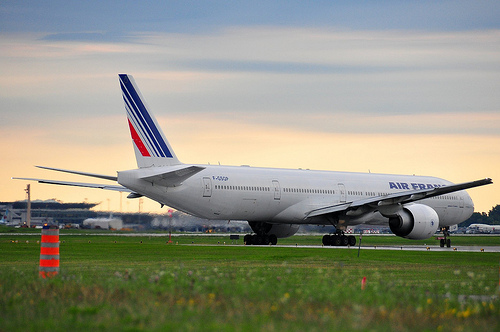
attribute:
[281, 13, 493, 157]
clouds — white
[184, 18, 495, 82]
clouds — white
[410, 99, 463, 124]
clouds — white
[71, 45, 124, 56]
cloud — white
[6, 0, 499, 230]
sky — blue